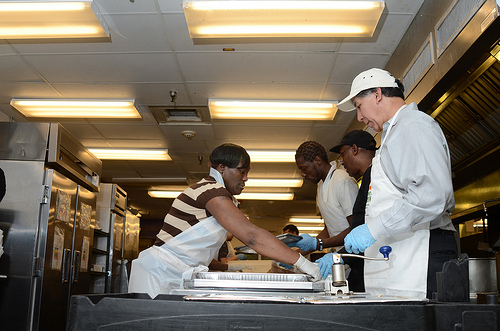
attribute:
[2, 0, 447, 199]
ceiling — white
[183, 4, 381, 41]
bulbs — fluorescent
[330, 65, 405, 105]
cap — white, snapback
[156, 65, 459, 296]
people — standing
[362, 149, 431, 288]
apron — white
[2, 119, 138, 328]
fridges — stainless steel, metallic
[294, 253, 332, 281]
gloves — latex, white, blue, hygenic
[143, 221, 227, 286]
apron — plastic, worn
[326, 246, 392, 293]
can opener — metal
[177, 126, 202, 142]
fire alarm — fire alarm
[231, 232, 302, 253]
tray — metal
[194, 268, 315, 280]
container — metal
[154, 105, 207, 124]
air vents — air vents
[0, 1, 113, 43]
light fixture — fluorescent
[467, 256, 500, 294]
pot — large, sitting